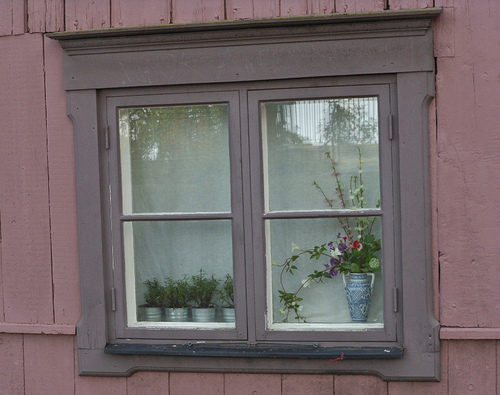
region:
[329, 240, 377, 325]
a blue decorated vase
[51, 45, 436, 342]
brown window with plants in it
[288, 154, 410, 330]
a vase with flowers in it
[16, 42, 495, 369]
a red house with a brown window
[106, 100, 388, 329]
the glass part of the window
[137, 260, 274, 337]
four plants in the window sill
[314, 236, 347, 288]
some purple flowers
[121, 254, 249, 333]
green plants in a pot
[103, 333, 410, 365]
the black part of the window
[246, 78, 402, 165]
reflection in the window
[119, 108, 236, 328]
The window pane is rectangular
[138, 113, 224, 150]
A tree is reflected in the window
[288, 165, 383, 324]
A plant in a vase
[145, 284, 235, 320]
Smaller plants in containers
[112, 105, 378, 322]
A window on a building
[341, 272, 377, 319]
A vase in the window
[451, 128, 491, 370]
A red wall by the window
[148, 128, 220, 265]
A white curtain behind the plants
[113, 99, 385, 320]
A window on the side of the building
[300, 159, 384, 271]
A green plant in the window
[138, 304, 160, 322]
a small metal can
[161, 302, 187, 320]
a small metal can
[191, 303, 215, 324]
a small metal can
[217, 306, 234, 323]
a small metal can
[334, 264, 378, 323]
a blue and white flower vase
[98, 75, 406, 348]
a brown wood framed window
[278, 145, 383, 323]
a bouquet of flowers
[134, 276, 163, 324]
a potted green plant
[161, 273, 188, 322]
a potted green plant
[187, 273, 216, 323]
a potted green plant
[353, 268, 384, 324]
vase in the window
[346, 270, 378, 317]
vase is blue and white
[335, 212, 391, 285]
flowers in the vase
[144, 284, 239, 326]
four plants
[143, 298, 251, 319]
plants are in metal buckets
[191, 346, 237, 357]
window sill is blue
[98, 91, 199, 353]
frame of window is plum purple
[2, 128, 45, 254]
wood is lavendar purple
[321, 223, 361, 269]
flowers are purple, red and white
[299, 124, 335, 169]
reflection in the glass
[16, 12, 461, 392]
a window with plants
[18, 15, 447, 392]
plants in a window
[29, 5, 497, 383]
a window that is closed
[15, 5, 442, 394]
a closed window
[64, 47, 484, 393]
a small window on a building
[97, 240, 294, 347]
five small plants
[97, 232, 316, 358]
five small plants on a window sill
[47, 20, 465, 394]
plants inside a window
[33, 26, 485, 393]
six plants inside a window